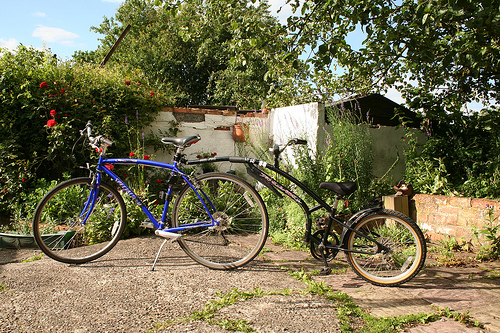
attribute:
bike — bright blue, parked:
[57, 144, 265, 271]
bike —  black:
[233, 166, 441, 278]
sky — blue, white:
[18, 0, 139, 54]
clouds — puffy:
[22, 0, 124, 60]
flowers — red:
[36, 77, 164, 186]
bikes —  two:
[43, 96, 448, 305]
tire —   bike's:
[27, 179, 134, 266]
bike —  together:
[25, 115, 440, 291]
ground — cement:
[1, 234, 498, 330]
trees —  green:
[73, 0, 316, 110]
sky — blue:
[56, 8, 81, 18]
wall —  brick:
[378, 186, 498, 258]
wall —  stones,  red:
[409, 193, 499, 248]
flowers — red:
[1, 77, 104, 133]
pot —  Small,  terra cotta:
[233, 124, 247, 146]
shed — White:
[135, 96, 425, 193]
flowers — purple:
[321, 88, 375, 178]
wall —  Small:
[406, 198, 496, 256]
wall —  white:
[269, 103, 322, 183]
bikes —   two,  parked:
[32, 120, 424, 287]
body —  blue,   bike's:
[75, 154, 215, 234]